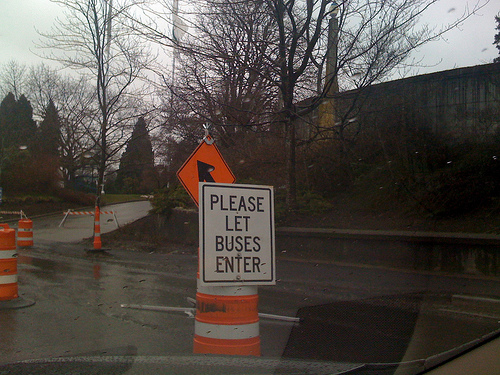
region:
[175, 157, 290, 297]
the letters are black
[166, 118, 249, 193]
the sign is orange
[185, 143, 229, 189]
the arrow is black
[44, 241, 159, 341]
the street is wet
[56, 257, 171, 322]
the street is black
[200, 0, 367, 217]
the trees are bare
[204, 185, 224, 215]
the letter is P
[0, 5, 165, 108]
the sky is overcast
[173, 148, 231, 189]
the arrow is pointing up and to the left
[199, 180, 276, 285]
A white sign that says please let buses enter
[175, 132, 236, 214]
An orange sign with an arrow.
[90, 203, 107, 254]
A long orange plastic traffic cone.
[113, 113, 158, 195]
An evergreen tree in the distance.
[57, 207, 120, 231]
An orange fence that blocks traffic.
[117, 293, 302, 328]
The white base of a sign on the street.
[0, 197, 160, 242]
A small road that is blocked off.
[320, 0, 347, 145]
A large lamp post in the distance.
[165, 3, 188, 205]
A flagpole with a white flag.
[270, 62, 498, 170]
A dark building in the distance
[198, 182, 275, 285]
White and black sign.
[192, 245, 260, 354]
Orange and white cone.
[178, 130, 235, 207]
Orange and black sign.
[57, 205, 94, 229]
Orange and white barrier.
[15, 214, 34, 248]
An orange traffic cone.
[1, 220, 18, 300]
A plastic traffic cone.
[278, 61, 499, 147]
A large gray building.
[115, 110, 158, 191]
A distant pine tree.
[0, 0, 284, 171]
A bright gray sky.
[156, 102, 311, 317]
sign says please let buses enter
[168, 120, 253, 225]
black arrow on orange sign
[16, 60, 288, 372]
the weather is wet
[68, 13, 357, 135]
the trees are bare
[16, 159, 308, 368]
traffic cones in street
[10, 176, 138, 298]
orange and white traffic cones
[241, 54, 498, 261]
a cement wall on hill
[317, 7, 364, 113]
a lamp post on wall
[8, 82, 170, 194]
pine trees in background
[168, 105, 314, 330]
the text is black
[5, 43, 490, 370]
Street under going construction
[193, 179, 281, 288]
Black and white traffic sign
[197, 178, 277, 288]
Sign reading please let buses enter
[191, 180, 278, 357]
Sign attached to traffic barrel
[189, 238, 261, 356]
Orange and white traffic barriel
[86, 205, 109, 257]
Orange and white traffic cone with rubber base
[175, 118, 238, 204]
Black arrow on orange traffic sign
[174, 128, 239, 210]
Sign requesting traffic merge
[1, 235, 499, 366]
Wet pavement in construction zone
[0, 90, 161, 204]
Evergreen trees in background